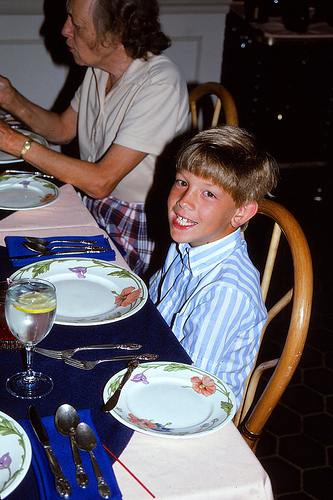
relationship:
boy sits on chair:
[147, 123, 280, 411] [208, 194, 311, 453]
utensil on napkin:
[8, 234, 108, 261] [4, 229, 121, 273]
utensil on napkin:
[10, 246, 113, 258] [4, 229, 121, 273]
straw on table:
[100, 441, 155, 498] [0, 118, 271, 499]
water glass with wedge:
[3, 275, 58, 402] [14, 292, 56, 314]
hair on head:
[174, 121, 283, 211] [164, 125, 271, 243]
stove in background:
[235, 29, 332, 173] [6, 7, 320, 195]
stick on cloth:
[98, 439, 164, 497] [176, 293, 258, 369]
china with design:
[101, 361, 239, 438] [109, 348, 248, 453]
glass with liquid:
[6, 277, 60, 351] [3, 281, 56, 344]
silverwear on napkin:
[15, 249, 107, 260] [6, 233, 116, 269]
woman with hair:
[56, 19, 208, 173] [97, 6, 227, 61]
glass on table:
[4, 277, 57, 399] [0, 118, 271, 499]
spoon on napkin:
[53, 402, 87, 488] [3, 234, 118, 263]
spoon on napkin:
[22, 237, 97, 248] [3, 234, 118, 263]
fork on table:
[24, 332, 154, 377] [0, 118, 271, 499]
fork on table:
[34, 341, 159, 372] [0, 118, 271, 499]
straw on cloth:
[96, 441, 155, 499] [3, 118, 280, 497]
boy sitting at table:
[147, 123, 271, 404] [0, 118, 271, 499]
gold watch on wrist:
[17, 134, 36, 163] [4, 88, 22, 117]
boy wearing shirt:
[147, 123, 271, 404] [146, 227, 266, 404]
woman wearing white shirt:
[0, 0, 193, 279] [66, 59, 199, 209]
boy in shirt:
[147, 123, 280, 411] [148, 227, 269, 418]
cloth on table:
[3, 118, 280, 497] [0, 196, 273, 494]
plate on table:
[5, 255, 149, 326] [0, 118, 271, 499]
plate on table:
[0, 173, 59, 209] [0, 165, 152, 336]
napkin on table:
[17, 407, 122, 497] [0, 161, 273, 499]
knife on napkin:
[28, 402, 72, 498] [28, 397, 105, 490]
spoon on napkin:
[53, 402, 88, 486] [28, 397, 105, 490]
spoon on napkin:
[72, 420, 111, 498] [28, 397, 105, 490]